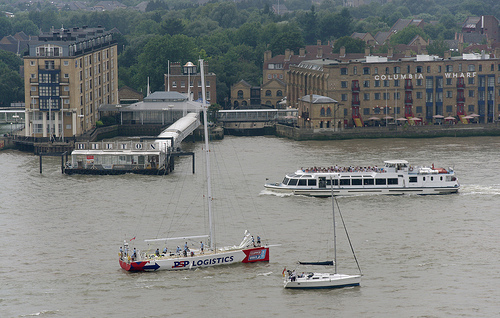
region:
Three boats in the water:
[55, 139, 460, 299]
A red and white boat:
[105, 232, 262, 292]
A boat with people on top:
[257, 140, 457, 211]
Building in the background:
[3, 17, 118, 175]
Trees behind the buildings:
[160, 7, 264, 54]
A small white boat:
[272, 233, 362, 303]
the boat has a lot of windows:
[290, 175, 390, 201]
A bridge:
[144, 105, 201, 170]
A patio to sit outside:
[330, 107, 485, 143]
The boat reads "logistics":
[186, 248, 241, 277]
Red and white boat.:
[75, 225, 270, 302]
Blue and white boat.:
[269, 237, 368, 316]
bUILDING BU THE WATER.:
[214, 40, 435, 164]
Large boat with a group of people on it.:
[270, 150, 465, 207]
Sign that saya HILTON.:
[65, 133, 188, 161]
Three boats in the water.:
[77, 145, 432, 315]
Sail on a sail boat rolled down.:
[286, 205, 356, 275]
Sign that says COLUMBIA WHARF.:
[365, 66, 487, 81]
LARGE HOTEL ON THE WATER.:
[282, 41, 490, 158]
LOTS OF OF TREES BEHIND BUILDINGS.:
[87, 0, 324, 91]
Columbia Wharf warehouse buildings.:
[284, 44, 496, 137]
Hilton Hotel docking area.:
[10, 33, 189, 189]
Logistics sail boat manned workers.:
[110, 220, 278, 280]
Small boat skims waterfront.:
[279, 235, 386, 306]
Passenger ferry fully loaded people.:
[262, 158, 482, 214]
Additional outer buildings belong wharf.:
[228, 36, 363, 116]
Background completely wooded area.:
[104, 1, 415, 33]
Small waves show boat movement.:
[250, 176, 492, 201]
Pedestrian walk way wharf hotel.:
[207, 101, 302, 123]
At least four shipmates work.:
[128, 239, 213, 265]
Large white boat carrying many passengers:
[262, 151, 461, 200]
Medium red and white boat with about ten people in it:
[116, 54, 269, 272]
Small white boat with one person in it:
[281, 166, 373, 296]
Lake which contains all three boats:
[0, 150, 497, 293]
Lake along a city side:
[10, 136, 480, 280]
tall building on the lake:
[15, 19, 126, 152]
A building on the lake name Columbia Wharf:
[280, 46, 497, 136]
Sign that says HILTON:
[68, 127, 159, 153]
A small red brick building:
[158, 58, 220, 108]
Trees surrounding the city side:
[2, 4, 406, 88]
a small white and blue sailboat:
[274, 182, 386, 300]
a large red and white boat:
[87, 47, 279, 282]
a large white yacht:
[251, 160, 478, 205]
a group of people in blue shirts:
[144, 236, 216, 258]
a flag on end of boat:
[274, 250, 302, 294]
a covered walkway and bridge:
[144, 105, 209, 165]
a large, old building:
[15, 12, 131, 149]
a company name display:
[368, 65, 485, 85]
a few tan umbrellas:
[361, 110, 490, 122]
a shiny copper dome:
[178, 57, 201, 71]